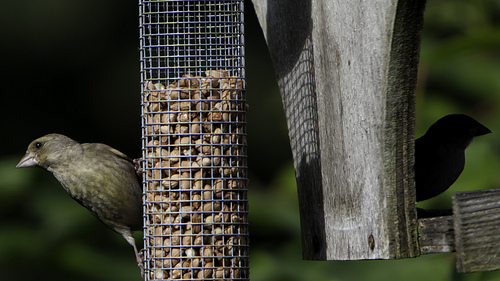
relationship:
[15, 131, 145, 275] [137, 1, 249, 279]
bird on side of bird feeder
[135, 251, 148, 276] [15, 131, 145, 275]
talon of bird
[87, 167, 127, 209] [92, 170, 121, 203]
belly has feathers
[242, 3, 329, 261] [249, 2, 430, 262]
reflection on plank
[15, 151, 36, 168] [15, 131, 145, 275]
beak on bird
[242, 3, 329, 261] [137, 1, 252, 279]
reflection of wire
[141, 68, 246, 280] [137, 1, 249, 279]
beans inside bird feeder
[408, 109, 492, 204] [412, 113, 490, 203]
shadow of bird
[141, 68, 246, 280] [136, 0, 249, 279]
beans inside wire box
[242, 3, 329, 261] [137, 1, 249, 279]
reflection cast by bird feeder